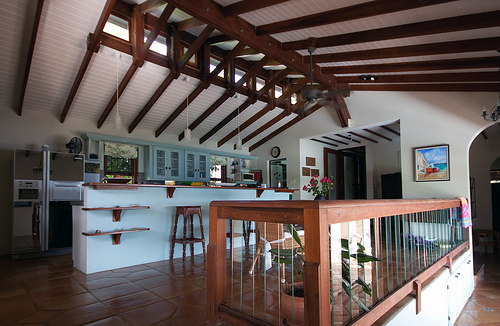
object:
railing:
[222, 219, 301, 323]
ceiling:
[1, 0, 500, 143]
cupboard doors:
[168, 151, 182, 179]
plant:
[269, 223, 381, 296]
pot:
[277, 282, 332, 326]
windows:
[105, 144, 137, 175]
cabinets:
[152, 148, 184, 180]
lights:
[237, 138, 243, 150]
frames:
[135, 12, 180, 64]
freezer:
[48, 148, 86, 256]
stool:
[170, 205, 209, 264]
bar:
[70, 183, 298, 274]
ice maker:
[14, 180, 44, 201]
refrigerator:
[13, 149, 82, 259]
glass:
[157, 149, 165, 175]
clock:
[271, 146, 282, 158]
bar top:
[82, 178, 299, 194]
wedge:
[166, 188, 176, 199]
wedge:
[256, 190, 265, 198]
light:
[184, 128, 192, 142]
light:
[113, 113, 121, 128]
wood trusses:
[96, 1, 346, 96]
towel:
[448, 196, 471, 229]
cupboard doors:
[152, 148, 168, 179]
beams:
[128, 0, 352, 98]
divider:
[208, 199, 473, 325]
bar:
[14, 147, 88, 250]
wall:
[253, 91, 469, 198]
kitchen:
[0, 0, 499, 326]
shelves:
[82, 203, 153, 221]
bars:
[209, 199, 462, 310]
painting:
[416, 149, 447, 180]